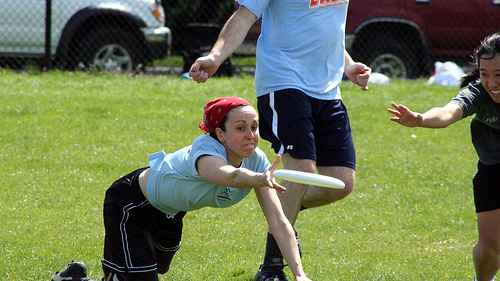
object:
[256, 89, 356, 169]
athletic shorts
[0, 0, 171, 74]
truck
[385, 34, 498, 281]
woman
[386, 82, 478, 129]
arm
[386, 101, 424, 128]
hand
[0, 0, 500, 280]
people playing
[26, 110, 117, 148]
green grass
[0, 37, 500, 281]
ground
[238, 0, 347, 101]
shirt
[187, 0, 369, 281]
player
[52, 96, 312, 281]
girl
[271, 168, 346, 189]
frisbee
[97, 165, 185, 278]
shorts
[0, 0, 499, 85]
fencing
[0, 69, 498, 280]
grass